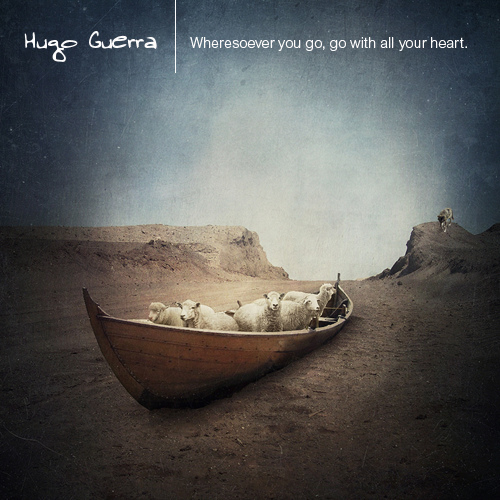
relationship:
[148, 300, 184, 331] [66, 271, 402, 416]
sheep contained inside boat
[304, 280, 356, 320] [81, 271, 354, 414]
open side of boat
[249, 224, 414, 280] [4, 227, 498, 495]
opening between partition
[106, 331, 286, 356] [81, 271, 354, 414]
lines on boat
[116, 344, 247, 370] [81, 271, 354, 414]
lines on boat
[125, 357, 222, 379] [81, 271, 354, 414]
lines on boat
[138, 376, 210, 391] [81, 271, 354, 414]
lines on boat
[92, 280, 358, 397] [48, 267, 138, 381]
boat has boat tip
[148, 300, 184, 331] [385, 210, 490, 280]
sheep back towards cliff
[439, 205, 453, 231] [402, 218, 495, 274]
man on rock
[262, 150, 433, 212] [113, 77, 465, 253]
skies have cloud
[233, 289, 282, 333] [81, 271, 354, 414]
animal standing in boat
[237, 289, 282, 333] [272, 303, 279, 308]
animal has nose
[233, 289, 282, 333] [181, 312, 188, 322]
animal has nose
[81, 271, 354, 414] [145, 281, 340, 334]
boat full of sheep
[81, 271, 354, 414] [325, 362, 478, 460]
boat sitting on dirt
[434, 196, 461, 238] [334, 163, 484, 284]
wolf standing in background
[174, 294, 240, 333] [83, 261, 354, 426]
sheep in boat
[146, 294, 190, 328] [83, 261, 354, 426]
sheep in boat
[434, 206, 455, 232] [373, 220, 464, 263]
object on rock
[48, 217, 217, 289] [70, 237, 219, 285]
land has row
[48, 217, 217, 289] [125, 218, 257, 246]
land has row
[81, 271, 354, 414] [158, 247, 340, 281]
boat on road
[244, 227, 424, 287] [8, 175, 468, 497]
pass through rise for road